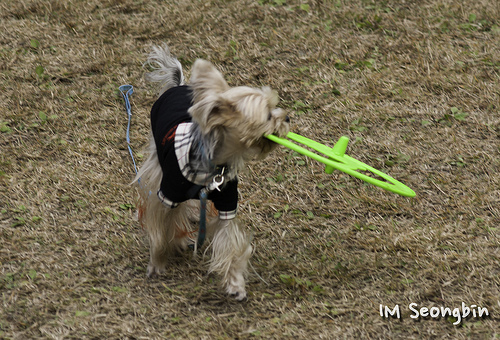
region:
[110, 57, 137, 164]
Blue leash on the ground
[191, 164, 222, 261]
Blue and red leash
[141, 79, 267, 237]
Black and red swetter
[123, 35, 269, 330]
Dog playing in the grass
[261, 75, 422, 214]
Puppy carrying a green thing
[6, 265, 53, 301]
Small patch of green grass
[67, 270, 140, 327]
Small patch of green grass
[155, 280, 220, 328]
Small patch of green grass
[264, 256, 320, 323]
Small patch of green grass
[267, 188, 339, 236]
Small patch of green grass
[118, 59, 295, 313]
small dog carrying green toy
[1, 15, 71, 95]
short brown and green grass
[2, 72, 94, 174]
short brown and green grass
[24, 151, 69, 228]
short brown and green grass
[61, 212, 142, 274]
short brown and green grass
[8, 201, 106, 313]
short brown and green grass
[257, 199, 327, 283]
short brown and green grass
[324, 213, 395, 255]
short brown and green grass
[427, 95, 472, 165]
short brown and green grass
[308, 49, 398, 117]
short brown and green grass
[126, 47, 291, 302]
A small dog wearing a shirt.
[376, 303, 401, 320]
IM in white letters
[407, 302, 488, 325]
Seongbin in white letters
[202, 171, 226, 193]
Silver connector of the leash to the collar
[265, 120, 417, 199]
A green hollow disc object in a dog's mouth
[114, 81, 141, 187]
A bright blue leash dragging behind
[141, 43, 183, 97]
A grey and white dog tail.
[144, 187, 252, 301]
Two hairy front legs of a dog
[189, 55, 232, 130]
Tan colored ears of a dog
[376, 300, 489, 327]
IM Seongbin in white lettering.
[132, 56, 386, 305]
Little dog ready to play.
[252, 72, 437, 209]
Mouth firmly green type saucer.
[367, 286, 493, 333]
Photographer IM Seongbin.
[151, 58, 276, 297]
Tight fit black white dog jacket.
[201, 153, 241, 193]
Silver collar clip for leash.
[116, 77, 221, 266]
Turquoise leash follows dog.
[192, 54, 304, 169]
Shaggy dog big tan ears.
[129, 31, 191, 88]
Short tail fluffy in wind.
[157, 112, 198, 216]
Plaid coat collar and sleeves.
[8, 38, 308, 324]
Ground covered dried grass.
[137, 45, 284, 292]
dog with long coat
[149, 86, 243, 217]
black shirt with plaid collar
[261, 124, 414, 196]
green plastic toy in mouth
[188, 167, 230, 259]
blue leash with metal clip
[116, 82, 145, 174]
blue leash on ground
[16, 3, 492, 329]
brown dried grass on ground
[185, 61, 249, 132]
two ears on head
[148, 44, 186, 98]
tail on back of dog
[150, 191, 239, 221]
plaid cuffs on shirt sleeves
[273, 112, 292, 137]
black nose on snout